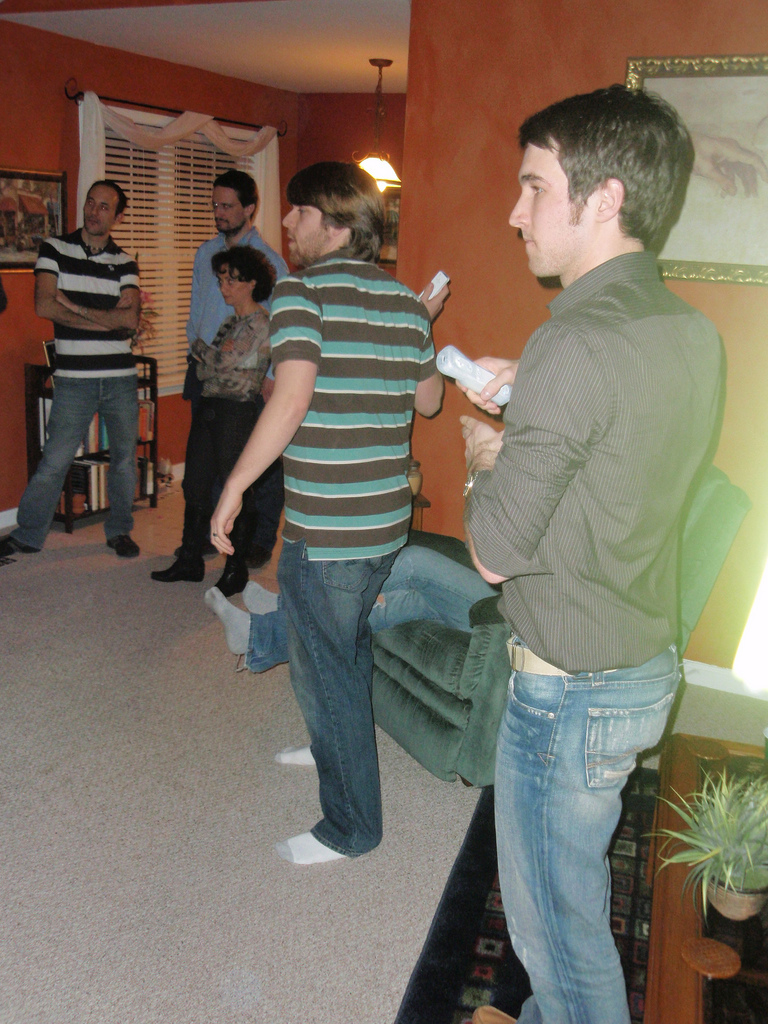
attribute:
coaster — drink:
[681, 934, 741, 974]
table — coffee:
[660, 960, 697, 999]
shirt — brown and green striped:
[269, 247, 439, 563]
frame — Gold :
[622, 51, 765, 285]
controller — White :
[436, 343, 512, 408]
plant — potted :
[650, 767, 765, 923]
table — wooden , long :
[637, 731, 765, 1021]